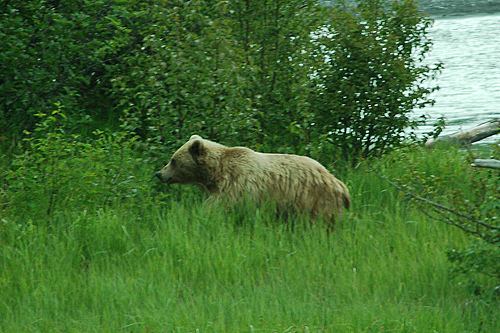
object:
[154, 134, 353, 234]
bear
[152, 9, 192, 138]
bushes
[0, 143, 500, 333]
grass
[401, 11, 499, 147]
water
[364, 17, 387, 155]
bushes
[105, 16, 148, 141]
bushes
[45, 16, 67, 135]
bushes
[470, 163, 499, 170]
tree trunk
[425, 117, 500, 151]
tree trunk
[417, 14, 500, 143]
river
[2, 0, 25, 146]
bushes